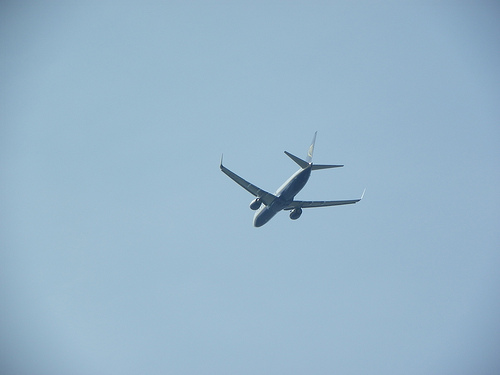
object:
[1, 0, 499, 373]
sky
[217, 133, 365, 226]
airplane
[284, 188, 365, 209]
right wing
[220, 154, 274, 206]
left wing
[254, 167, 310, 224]
bottom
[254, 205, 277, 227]
front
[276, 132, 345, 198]
back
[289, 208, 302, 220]
engine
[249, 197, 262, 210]
engine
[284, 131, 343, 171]
tip